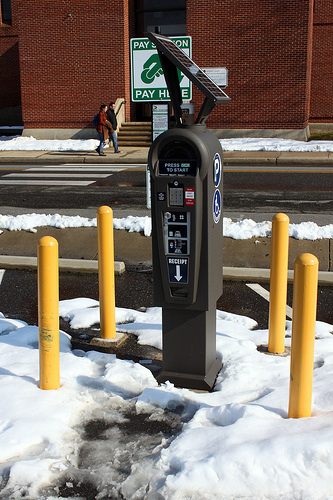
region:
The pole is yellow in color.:
[91, 203, 119, 340]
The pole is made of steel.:
[90, 205, 122, 339]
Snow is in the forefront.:
[223, 438, 330, 498]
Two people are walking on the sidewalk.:
[92, 101, 122, 156]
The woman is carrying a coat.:
[92, 104, 111, 156]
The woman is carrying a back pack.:
[91, 104, 110, 154]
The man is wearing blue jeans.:
[106, 101, 121, 153]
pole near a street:
[287, 249, 313, 420]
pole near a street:
[263, 201, 287, 356]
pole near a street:
[96, 203, 120, 339]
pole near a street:
[25, 230, 71, 386]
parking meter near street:
[121, 23, 243, 384]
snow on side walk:
[202, 433, 260, 479]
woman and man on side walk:
[90, 99, 124, 155]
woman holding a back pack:
[92, 100, 110, 158]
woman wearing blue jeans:
[92, 102, 111, 158]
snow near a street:
[22, 214, 75, 229]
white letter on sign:
[132, 40, 138, 48]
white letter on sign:
[136, 41, 143, 49]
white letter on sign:
[142, 39, 150, 48]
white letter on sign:
[175, 39, 181, 48]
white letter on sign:
[181, 37, 188, 47]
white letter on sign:
[134, 89, 141, 99]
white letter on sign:
[141, 89, 149, 99]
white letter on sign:
[147, 88, 155, 98]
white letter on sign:
[158, 88, 166, 97]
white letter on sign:
[181, 88, 191, 98]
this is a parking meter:
[75, 14, 268, 430]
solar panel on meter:
[139, 15, 250, 112]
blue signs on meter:
[206, 141, 240, 233]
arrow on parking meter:
[152, 246, 198, 301]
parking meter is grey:
[133, 90, 230, 420]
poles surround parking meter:
[16, 174, 332, 432]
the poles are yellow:
[21, 173, 331, 437]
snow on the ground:
[8, 276, 331, 498]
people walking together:
[84, 84, 155, 171]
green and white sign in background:
[113, 12, 213, 126]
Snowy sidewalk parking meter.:
[143, 63, 228, 392]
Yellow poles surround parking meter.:
[26, 211, 321, 425]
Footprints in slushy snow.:
[62, 409, 185, 499]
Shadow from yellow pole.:
[73, 372, 265, 413]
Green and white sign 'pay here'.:
[130, 33, 199, 107]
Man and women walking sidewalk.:
[95, 99, 123, 157]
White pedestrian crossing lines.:
[2, 161, 144, 191]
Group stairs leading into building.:
[118, 118, 154, 150]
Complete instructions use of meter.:
[157, 158, 200, 288]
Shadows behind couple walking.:
[41, 143, 128, 155]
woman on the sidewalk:
[93, 103, 111, 153]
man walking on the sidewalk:
[105, 99, 123, 154]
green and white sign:
[129, 35, 193, 105]